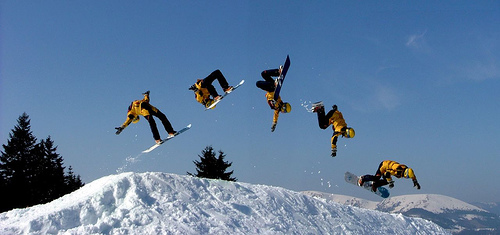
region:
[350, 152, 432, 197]
man in the air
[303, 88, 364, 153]
man in the sky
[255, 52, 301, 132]
man in the sky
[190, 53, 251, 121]
man in the sky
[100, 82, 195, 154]
man in the sky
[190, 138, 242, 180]
tree near a hill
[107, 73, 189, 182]
a person that is snowboarding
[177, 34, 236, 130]
a person that is snowboarding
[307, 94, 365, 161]
a person that is snowboarding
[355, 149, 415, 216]
a person that is snowboarding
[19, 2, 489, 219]
a sky that is blue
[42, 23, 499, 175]
a clear blue sky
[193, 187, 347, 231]
a ground covered in snow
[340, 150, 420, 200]
snowboarder leaning forward in air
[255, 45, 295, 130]
snowboarder upside down in air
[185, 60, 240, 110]
snowboarder backwards on bent knees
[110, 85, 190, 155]
snowboarder upright and leaning back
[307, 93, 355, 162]
snowboarder upside down with bent knees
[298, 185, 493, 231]
snow-capped mountains in distance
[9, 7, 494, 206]
clear blue sky with the faintest of clouds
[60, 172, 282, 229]
slanted marks across the snow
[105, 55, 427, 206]
Snowboarders are in a line.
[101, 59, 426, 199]
People are snowboarding.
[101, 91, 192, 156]
The snowboarder is wearing yellow and black.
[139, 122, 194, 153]
The snowboard is white.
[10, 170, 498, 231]
The hills are covered in snow.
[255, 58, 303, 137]
The snowboarder is upside down.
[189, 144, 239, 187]
The tree has no snow.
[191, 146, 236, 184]
The tree is green.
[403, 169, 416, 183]
The helmet is yellow.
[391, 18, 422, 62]
white clouds in blue sky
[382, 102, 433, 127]
white clouds in blue sky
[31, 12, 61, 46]
white clouds in blue sky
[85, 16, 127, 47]
white clouds in blue sky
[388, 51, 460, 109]
white clouds in blue sky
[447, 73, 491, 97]
white clouds in blue sky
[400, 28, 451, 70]
white clouds in blue sky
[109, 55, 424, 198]
snowboarder with different positions during a jump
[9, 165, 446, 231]
wide mound of marked snow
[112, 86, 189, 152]
snowboarder leaning back with arms out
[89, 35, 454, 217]
a jump of sequence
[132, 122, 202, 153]
this is a snowboard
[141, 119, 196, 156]
the snow board is white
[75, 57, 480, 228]
person is doing a trick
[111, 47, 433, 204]
person in mid air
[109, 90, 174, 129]
a yellow and black jacket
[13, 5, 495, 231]
a bright and clear day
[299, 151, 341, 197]
snow in the air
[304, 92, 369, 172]
person is upside down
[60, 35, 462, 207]
the person is snowboarding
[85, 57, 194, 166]
he has his arms spread out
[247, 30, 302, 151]
the person is upside down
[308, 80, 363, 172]
the snowboarder is upside down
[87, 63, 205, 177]
the person is preparing to flip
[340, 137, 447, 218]
the person is preparing to land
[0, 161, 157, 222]
this is a ramp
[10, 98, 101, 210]
the trees are dark